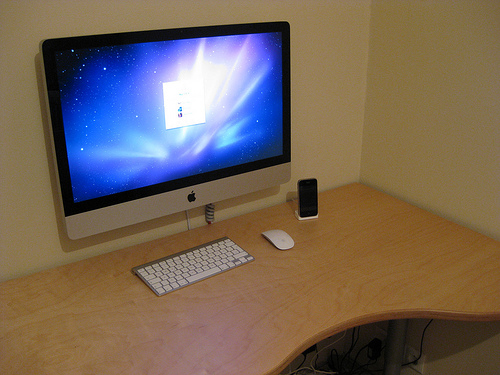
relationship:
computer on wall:
[37, 21, 291, 241] [0, 2, 371, 282]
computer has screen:
[37, 21, 291, 241] [53, 30, 283, 204]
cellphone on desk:
[297, 177, 317, 217] [0, 179, 499, 375]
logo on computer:
[186, 190, 197, 203] [37, 21, 291, 241]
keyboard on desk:
[131, 235, 255, 297] [0, 179, 499, 375]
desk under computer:
[0, 179, 499, 375] [37, 21, 291, 241]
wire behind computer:
[184, 210, 191, 233] [37, 21, 291, 241]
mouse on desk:
[259, 229, 294, 251] [0, 179, 499, 375]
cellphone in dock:
[297, 177, 317, 217] [294, 209, 319, 221]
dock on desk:
[294, 209, 319, 221] [0, 179, 499, 375]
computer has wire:
[37, 21, 291, 241] [184, 210, 191, 233]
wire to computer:
[184, 210, 191, 233] [37, 21, 291, 241]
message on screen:
[161, 75, 206, 130] [53, 30, 283, 204]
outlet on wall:
[403, 347, 427, 373] [400, 318, 497, 375]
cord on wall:
[402, 316, 434, 367] [400, 318, 497, 375]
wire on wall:
[184, 210, 191, 233] [0, 2, 371, 282]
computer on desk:
[37, 21, 291, 241] [0, 179, 499, 375]